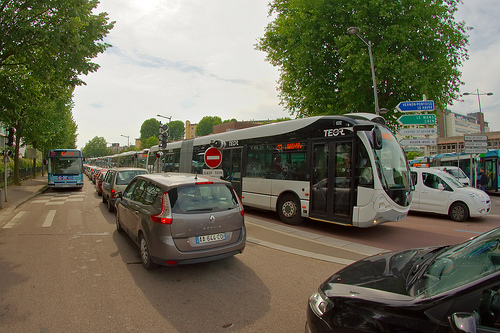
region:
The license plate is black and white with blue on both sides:
[185, 229, 240, 251]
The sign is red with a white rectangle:
[191, 133, 246, 211]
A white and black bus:
[179, 87, 417, 244]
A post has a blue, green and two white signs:
[391, 89, 444, 154]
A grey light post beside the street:
[339, 19, 420, 162]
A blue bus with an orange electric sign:
[36, 138, 90, 207]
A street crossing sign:
[13, 202, 153, 241]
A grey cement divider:
[250, 196, 384, 281]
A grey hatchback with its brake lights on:
[121, 161, 256, 273]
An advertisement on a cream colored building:
[418, 91, 486, 164]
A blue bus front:
[46, 142, 87, 192]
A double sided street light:
[462, 85, 498, 133]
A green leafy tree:
[277, 2, 441, 105]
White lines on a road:
[245, 216, 369, 269]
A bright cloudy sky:
[124, 12, 240, 99]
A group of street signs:
[396, 94, 436, 154]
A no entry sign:
[200, 144, 226, 170]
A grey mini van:
[113, 172, 248, 272]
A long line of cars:
[86, 161, 144, 207]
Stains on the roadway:
[60, 225, 106, 290]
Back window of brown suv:
[161, 173, 246, 218]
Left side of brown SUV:
[112, 170, 168, 250]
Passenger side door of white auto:
[415, 163, 478, 228]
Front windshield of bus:
[345, 105, 421, 223]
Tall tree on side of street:
[255, 10, 366, 110]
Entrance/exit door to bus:
[307, 122, 367, 223]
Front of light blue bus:
[36, 141, 94, 196]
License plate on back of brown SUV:
[175, 225, 252, 257]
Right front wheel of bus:
[271, 185, 321, 227]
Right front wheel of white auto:
[445, 194, 477, 224]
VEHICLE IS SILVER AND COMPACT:
[66, 156, 284, 316]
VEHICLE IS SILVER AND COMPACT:
[115, 154, 262, 272]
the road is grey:
[47, 266, 242, 313]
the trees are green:
[270, 35, 450, 101]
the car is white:
[420, 170, 497, 225]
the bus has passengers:
[196, 127, 400, 207]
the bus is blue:
[34, 145, 107, 200]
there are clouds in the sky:
[135, 45, 259, 100]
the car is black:
[324, 242, 498, 326]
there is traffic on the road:
[47, 133, 329, 250]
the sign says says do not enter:
[189, 143, 244, 169]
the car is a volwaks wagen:
[125, 181, 271, 266]